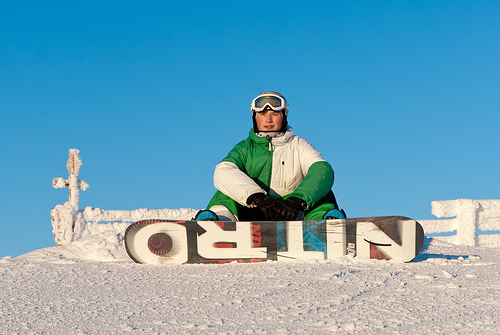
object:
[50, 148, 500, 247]
fence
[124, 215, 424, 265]
colored snowboard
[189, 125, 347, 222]
snow suit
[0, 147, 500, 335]
snow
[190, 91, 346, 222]
person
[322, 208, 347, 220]
boots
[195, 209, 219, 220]
boots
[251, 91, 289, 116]
tan helmet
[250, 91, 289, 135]
head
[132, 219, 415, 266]
letters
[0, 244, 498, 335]
hill